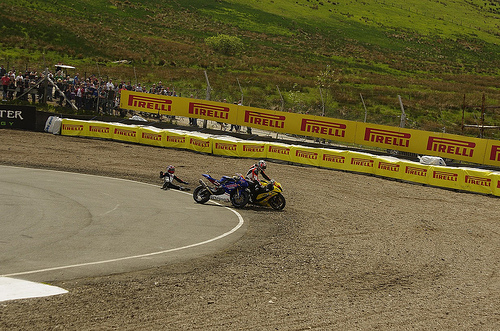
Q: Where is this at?
A: A racetrack.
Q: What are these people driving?
A: Motorcycles.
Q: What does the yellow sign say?
A: Pirelli.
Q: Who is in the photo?
A: Racers.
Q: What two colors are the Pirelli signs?
A: Red and yellow.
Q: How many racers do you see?
A: 2.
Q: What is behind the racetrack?
A: A field.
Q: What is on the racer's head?
A: A helmet.